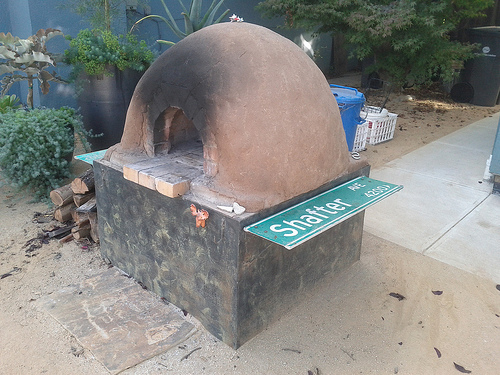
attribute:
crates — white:
[354, 99, 401, 152]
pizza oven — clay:
[111, 24, 408, 264]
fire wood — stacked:
[52, 175, 96, 242]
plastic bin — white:
[361, 110, 398, 142]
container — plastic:
[76, 63, 157, 155]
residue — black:
[155, 67, 204, 104]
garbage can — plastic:
[450, 25, 499, 106]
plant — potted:
[21, 57, 87, 202]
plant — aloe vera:
[150, 2, 227, 34]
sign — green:
[243, 173, 406, 250]